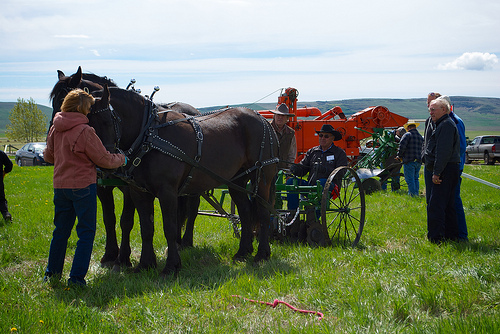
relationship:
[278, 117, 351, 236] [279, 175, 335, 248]
man sitting on plow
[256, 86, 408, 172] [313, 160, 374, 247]
equipment has wheel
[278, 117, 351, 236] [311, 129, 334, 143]
man wearing glasses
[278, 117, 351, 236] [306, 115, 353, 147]
man wearing hat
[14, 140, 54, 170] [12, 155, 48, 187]
cars in field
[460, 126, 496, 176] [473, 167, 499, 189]
truck in a field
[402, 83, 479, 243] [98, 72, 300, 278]
people looking at horses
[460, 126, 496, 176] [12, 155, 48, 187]
truck in field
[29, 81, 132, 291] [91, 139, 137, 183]
woman helping harness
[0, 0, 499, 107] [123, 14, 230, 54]
cloud in sky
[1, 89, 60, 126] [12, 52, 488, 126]
mountain in background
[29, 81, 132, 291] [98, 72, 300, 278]
woman next to horses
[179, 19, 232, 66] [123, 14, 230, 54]
cloud in sky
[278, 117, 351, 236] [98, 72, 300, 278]
man sitting behind horses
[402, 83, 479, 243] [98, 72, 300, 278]
men looking at horses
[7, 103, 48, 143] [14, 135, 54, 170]
trees behind cars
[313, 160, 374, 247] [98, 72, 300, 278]
device connected to horses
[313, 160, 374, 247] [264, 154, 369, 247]
wheels on contraption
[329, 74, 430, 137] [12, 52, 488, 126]
hills in background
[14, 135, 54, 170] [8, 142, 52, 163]
vehicle on left